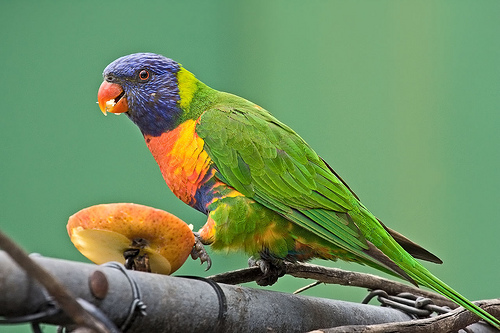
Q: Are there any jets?
A: No, there are no jets.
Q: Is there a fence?
A: No, there are no fences.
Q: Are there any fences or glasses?
A: No, there are no fences or glasses.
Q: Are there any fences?
A: No, there are no fences.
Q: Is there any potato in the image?
A: Yes, there is a potato.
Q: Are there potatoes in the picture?
A: Yes, there is a potato.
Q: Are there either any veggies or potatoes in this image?
A: Yes, there is a potato.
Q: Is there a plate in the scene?
A: No, there are no plates.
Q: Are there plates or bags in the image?
A: No, there are no plates or bags.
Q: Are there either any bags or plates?
A: No, there are no plates or bags.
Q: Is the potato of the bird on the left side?
A: Yes, the potato is on the left of the image.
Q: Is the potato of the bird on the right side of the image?
A: No, the potato is on the left of the image.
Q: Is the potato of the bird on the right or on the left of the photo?
A: The potato is on the left of the image.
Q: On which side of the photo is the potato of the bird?
A: The potato is on the left of the image.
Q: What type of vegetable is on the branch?
A: The vegetable is a potato.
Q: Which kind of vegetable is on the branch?
A: The vegetable is a potato.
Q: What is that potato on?
A: The potato is on the branch.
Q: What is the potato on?
A: The potato is on the branch.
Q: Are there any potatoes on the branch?
A: Yes, there is a potato on the branch.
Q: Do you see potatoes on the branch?
A: Yes, there is a potato on the branch.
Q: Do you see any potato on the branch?
A: Yes, there is a potato on the branch.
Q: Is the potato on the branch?
A: Yes, the potato is on the branch.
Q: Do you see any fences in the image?
A: No, there are no fences.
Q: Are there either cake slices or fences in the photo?
A: No, there are no fences or cake slices.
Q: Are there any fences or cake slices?
A: No, there are no fences or cake slices.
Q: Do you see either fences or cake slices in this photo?
A: No, there are no fences or cake slices.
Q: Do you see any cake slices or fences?
A: No, there are no fences or cake slices.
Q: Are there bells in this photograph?
A: No, there are no bells.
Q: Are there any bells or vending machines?
A: No, there are no bells or vending machines.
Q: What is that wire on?
A: The wire is on the branch.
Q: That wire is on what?
A: The wire is on the branch.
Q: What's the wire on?
A: The wire is on the branch.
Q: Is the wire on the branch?
A: Yes, the wire is on the branch.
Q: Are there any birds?
A: Yes, there is a bird.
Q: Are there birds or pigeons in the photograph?
A: Yes, there is a bird.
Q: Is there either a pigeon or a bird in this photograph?
A: Yes, there is a bird.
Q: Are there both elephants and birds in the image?
A: No, there is a bird but no elephants.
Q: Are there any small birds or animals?
A: Yes, there is a small bird.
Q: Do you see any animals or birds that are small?
A: Yes, the bird is small.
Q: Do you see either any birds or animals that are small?
A: Yes, the bird is small.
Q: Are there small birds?
A: Yes, there is a small bird.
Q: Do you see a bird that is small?
A: Yes, there is a bird that is small.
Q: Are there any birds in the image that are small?
A: Yes, there is a bird that is small.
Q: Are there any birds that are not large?
A: Yes, there is a small bird.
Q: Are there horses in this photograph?
A: No, there are no horses.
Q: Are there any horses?
A: No, there are no horses.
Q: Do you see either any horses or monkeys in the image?
A: No, there are no horses or monkeys.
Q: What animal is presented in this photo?
A: The animal is a bird.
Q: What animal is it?
A: The animal is a bird.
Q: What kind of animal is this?
A: This is a bird.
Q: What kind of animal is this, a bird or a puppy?
A: This is a bird.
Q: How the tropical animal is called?
A: The animal is a bird.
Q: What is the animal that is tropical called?
A: The animal is a bird.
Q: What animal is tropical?
A: The animal is a bird.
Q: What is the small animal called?
A: The animal is a bird.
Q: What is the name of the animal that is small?
A: The animal is a bird.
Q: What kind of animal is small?
A: The animal is a bird.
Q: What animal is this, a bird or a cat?
A: This is a bird.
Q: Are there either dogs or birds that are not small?
A: No, there is a bird but it is small.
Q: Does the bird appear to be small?
A: Yes, the bird is small.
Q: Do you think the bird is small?
A: Yes, the bird is small.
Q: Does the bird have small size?
A: Yes, the bird is small.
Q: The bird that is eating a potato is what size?
A: The bird is small.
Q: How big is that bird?
A: The bird is small.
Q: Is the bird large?
A: No, the bird is small.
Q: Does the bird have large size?
A: No, the bird is small.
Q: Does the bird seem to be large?
A: No, the bird is small.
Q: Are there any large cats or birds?
A: No, there is a bird but it is small.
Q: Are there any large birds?
A: No, there is a bird but it is small.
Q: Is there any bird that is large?
A: No, there is a bird but it is small.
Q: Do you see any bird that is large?
A: No, there is a bird but it is small.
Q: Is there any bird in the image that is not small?
A: No, there is a bird but it is small.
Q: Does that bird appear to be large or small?
A: The bird is small.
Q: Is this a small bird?
A: Yes, this is a small bird.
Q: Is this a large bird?
A: No, this is a small bird.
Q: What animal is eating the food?
A: The bird is eating the food.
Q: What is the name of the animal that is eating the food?
A: The animal is a bird.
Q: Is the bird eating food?
A: Yes, the bird is eating food.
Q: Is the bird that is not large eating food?
A: Yes, the bird is eating food.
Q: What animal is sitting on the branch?
A: The bird is sitting on the branch.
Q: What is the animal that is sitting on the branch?
A: The animal is a bird.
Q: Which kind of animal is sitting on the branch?
A: The animal is a bird.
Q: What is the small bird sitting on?
A: The bird is sitting on the branch.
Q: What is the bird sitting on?
A: The bird is sitting on the branch.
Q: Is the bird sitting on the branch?
A: Yes, the bird is sitting on the branch.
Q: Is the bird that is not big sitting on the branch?
A: Yes, the bird is sitting on the branch.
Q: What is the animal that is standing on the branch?
A: The animal is a bird.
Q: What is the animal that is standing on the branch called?
A: The animal is a bird.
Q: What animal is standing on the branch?
A: The animal is a bird.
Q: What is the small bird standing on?
A: The bird is standing on the branch.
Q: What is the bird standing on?
A: The bird is standing on the branch.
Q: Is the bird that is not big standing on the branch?
A: Yes, the bird is standing on the branch.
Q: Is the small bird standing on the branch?
A: Yes, the bird is standing on the branch.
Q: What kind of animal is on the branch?
A: The animal is a bird.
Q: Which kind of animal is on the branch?
A: The animal is a bird.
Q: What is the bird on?
A: The bird is on the branch.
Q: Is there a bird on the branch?
A: Yes, there is a bird on the branch.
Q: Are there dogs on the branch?
A: No, there is a bird on the branch.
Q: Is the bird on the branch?
A: Yes, the bird is on the branch.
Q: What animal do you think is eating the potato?
A: The bird is eating the potato.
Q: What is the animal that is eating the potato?
A: The animal is a bird.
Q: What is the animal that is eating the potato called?
A: The animal is a bird.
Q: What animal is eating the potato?
A: The animal is a bird.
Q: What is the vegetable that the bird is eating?
A: The vegetable is a potato.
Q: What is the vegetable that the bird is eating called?
A: The vegetable is a potato.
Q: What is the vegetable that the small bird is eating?
A: The vegetable is a potato.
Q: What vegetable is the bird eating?
A: The bird is eating a potato.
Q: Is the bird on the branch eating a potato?
A: Yes, the bird is eating a potato.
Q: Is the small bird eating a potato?
A: Yes, the bird is eating a potato.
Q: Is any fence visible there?
A: No, there are no fences.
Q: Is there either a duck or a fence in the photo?
A: No, there are no fences or ducks.